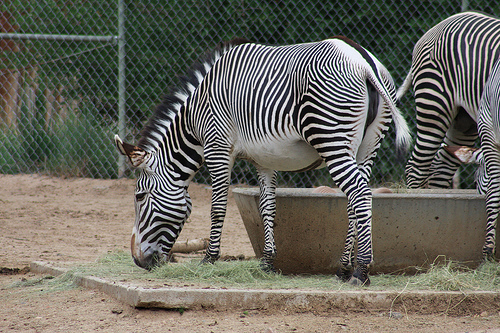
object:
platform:
[28, 248, 500, 317]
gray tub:
[234, 185, 499, 273]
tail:
[364, 63, 417, 157]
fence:
[0, 0, 499, 183]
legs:
[308, 139, 374, 274]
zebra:
[111, 35, 413, 288]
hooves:
[347, 273, 370, 289]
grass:
[0, 255, 499, 297]